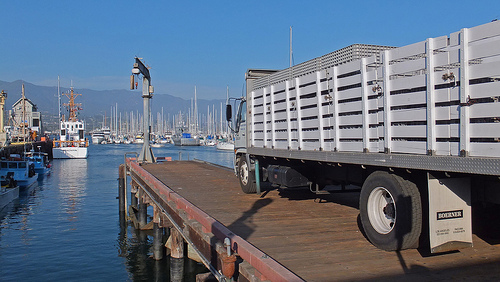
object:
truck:
[187, 18, 500, 252]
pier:
[113, 141, 499, 282]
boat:
[44, 80, 96, 161]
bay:
[0, 135, 234, 281]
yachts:
[169, 125, 204, 148]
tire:
[357, 170, 427, 253]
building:
[5, 78, 48, 162]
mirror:
[220, 101, 237, 124]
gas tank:
[261, 157, 320, 190]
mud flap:
[424, 165, 477, 254]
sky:
[5, 0, 499, 98]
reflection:
[48, 157, 91, 227]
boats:
[0, 157, 39, 185]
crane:
[122, 51, 163, 166]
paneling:
[248, 21, 500, 158]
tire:
[236, 150, 263, 194]